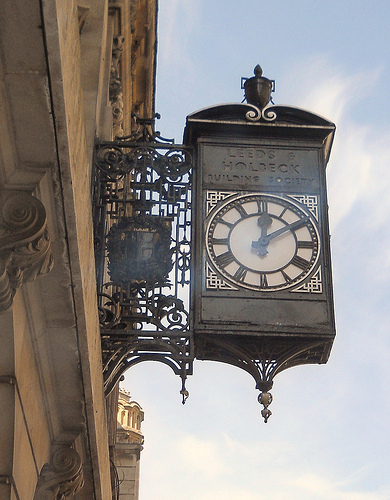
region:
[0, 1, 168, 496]
an old looking building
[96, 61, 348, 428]
an old looking clock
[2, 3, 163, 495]
the building is tan and dark brown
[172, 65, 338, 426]
the clock is dark brown and white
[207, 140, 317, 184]
words are on the clock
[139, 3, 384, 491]
the sky is a beautiful blue color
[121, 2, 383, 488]
clouds are in the sky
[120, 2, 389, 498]
the clouds are fuzzy looking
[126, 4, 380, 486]
the clouds are a pretty white color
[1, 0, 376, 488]
it is daytime outside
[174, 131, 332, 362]
clock on side of building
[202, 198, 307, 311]
clock has white face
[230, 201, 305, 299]
clock has roman numerals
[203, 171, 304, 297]
roman numerals are black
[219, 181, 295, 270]
clock hands are black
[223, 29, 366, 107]
blue and white sky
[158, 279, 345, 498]
wispy clouds in sky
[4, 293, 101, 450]
side of building is tan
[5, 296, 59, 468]
stone construction on building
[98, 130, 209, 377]
black metal connector for clock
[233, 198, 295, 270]
White face on clock.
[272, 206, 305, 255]
Black hand on clock.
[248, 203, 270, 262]
Black hand on clock.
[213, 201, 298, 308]
Black numbers on clock.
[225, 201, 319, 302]
Numbers on clock are roman numeral.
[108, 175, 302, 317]
Clock attached to side of building.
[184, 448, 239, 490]
White clouds in sky.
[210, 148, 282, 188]
Words above clock.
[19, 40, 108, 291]
Large building near clock.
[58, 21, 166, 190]
Building near clock is tall.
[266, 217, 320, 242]
long hand on clock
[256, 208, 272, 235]
short hand on clock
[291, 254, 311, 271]
roman numeral on clock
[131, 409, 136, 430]
window on tall building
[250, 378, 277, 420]
pointed bottom on clock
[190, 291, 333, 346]
metal box around clock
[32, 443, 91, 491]
design on concrete building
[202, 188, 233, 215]
ornate design around clock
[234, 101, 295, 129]
swirl design on top of clock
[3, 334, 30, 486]
corner of tall building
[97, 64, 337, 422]
clock on iron bracket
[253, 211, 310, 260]
black hands on clock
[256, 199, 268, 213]
roman numeral number twelve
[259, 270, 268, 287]
roman numeral number six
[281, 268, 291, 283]
roman numeral number five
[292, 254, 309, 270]
roman numeral number four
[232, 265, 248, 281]
roman numeral number six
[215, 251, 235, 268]
roman numeral number eight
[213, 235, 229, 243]
roman numeral number nine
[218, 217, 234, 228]
roman numeral number ten